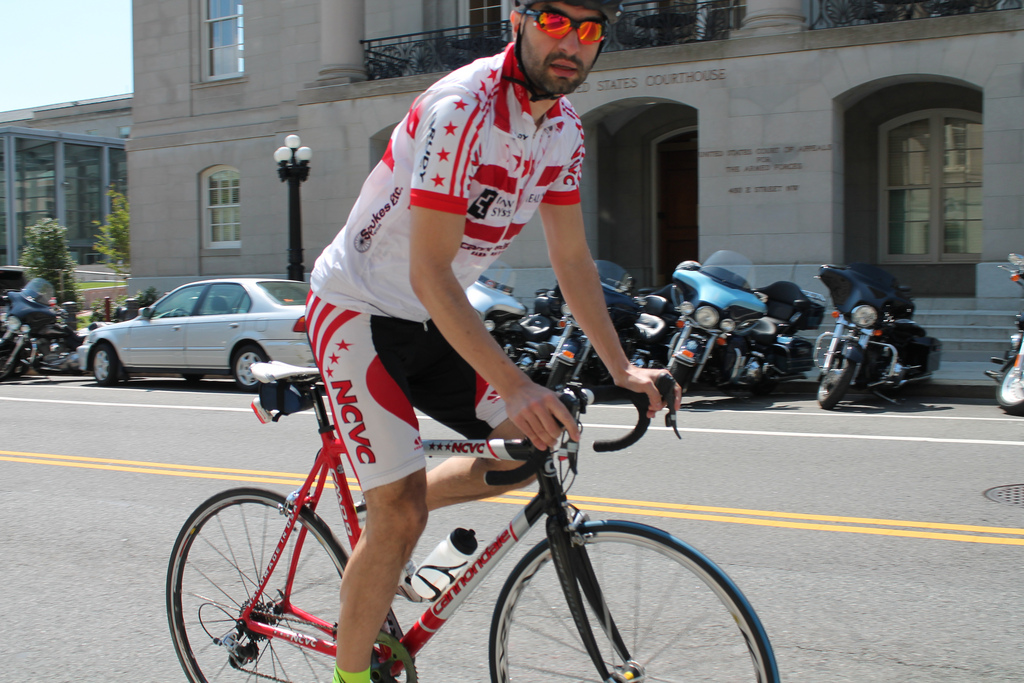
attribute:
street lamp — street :
[270, 127, 316, 274]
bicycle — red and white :
[163, 371, 775, 678]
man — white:
[307, 4, 684, 677]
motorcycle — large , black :
[811, 261, 937, 411]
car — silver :
[72, 272, 314, 404]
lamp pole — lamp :
[271, 131, 315, 281]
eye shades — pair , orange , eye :
[526, 1, 609, 43]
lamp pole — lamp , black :
[281, 179, 307, 279]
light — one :
[294, 148, 310, 161]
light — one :
[281, 133, 307, 147]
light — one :
[271, 150, 289, 168]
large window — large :
[875, 110, 975, 266]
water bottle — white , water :
[411, 526, 481, 594]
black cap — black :
[448, 524, 475, 553]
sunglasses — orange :
[525, 2, 610, 44]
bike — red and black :
[163, 369, 781, 679]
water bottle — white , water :
[402, 526, 476, 600]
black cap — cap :
[446, 524, 481, 553]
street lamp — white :
[284, 127, 304, 153]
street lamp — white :
[296, 144, 314, 166]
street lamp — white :
[271, 144, 291, 166]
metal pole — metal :
[279, 159, 310, 278]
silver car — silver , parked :
[85, 274, 306, 381]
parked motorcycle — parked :
[813, 258, 937, 412]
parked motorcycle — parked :
[664, 248, 824, 411]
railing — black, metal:
[344, 5, 723, 55]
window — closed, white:
[880, 109, 993, 250]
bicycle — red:
[154, 336, 796, 678]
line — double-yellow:
[5, 435, 1021, 554]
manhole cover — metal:
[984, 465, 1023, 511]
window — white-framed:
[200, 158, 253, 254]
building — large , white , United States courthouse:
[126, 5, 1023, 379]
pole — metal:
[282, 186, 313, 301]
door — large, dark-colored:
[656, 130, 709, 290]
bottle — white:
[407, 515, 477, 602]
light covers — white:
[269, 122, 315, 162]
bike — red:
[152, 344, 798, 677]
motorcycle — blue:
[658, 255, 823, 392]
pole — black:
[269, 160, 317, 288]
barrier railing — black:
[346, 20, 519, 81]